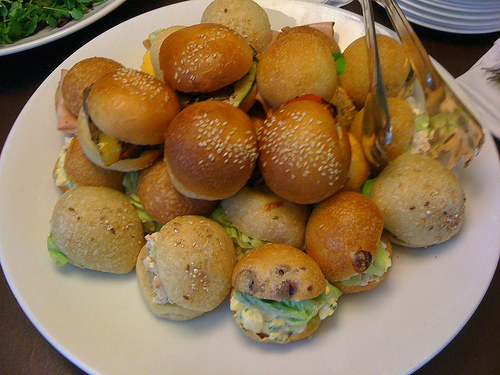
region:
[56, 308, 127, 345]
The plate is white.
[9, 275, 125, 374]
The plate is round.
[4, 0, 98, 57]
The lettuce is green.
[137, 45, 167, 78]
The cheese is orange.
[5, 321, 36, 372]
The table is brown.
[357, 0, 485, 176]
The tongs are silver.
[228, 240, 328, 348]
The sandwich is small.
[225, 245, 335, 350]
The sandwich bread is brown.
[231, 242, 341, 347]
The lettuce on the sandwich is green.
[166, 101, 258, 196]
There are seeds on the bun.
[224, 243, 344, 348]
Mini sandwich on plate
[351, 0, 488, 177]
Shiny silver tongs on plate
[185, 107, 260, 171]
Sesame seeds on bun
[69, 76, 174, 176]
Minature sandwich on plate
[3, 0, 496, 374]
Circular white plate with food on it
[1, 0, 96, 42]
Vibrant green leaves on plate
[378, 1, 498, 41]
Stack o blue plates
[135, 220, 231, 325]
Light brown miniature sandwich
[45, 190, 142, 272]
miniature circle of dough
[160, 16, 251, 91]
Bun with sesame seeds on it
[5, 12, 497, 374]
a plate full of food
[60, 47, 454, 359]
mini sandwiches on the plate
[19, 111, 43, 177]
the plate is white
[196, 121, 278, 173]
the bread has sesame seeds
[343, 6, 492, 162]
a pair of tongs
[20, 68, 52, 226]
the plate is round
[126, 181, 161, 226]
lettuce in the sandwiches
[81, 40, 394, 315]
the sandwiches are ready to eat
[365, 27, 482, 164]
the tongs are silver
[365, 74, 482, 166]
the tongs are made of metal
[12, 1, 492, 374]
several mini burgers on a plate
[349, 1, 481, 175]
tongs leaning on the plate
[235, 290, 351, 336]
lettuce sticking out from under the bread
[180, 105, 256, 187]
white seeds on top of the bread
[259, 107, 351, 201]
bread covered in seseame seeds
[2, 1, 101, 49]
green lettuce on the edge of the plate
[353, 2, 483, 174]
a pair of silver tongs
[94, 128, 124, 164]
cheese hanging out from the bun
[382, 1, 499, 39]
a stack of white plates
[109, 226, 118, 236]
speck on the bun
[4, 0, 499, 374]
plate filled with mini burgers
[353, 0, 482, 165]
tongs laying on the plate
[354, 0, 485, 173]
pair of silver tongs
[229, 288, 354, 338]
lettuce hanging out from under the bread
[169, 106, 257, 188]
white specks on the bun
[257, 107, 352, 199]
bun covered in seeds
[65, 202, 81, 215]
black dot on the bread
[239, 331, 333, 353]
shadow on the plate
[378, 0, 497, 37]
a stack of plates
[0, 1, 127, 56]
dark green lettuce on the edge of the plate